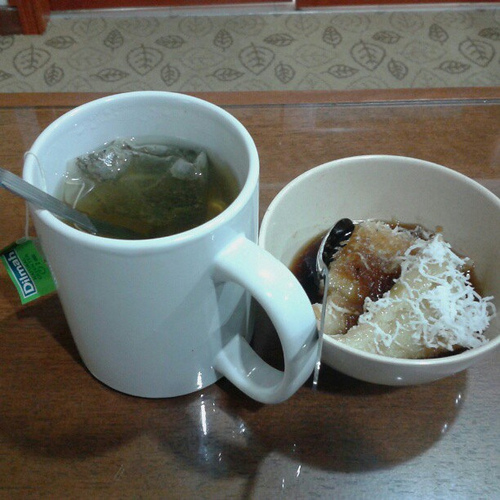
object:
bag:
[0, 240, 56, 306]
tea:
[83, 103, 227, 220]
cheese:
[411, 249, 486, 349]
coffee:
[295, 252, 326, 294]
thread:
[12, 152, 47, 242]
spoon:
[0, 167, 97, 232]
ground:
[269, 137, 317, 170]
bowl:
[258, 154, 500, 387]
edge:
[279, 455, 421, 475]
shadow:
[0, 383, 473, 481]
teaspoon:
[312, 217, 355, 385]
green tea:
[53, 137, 239, 241]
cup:
[22, 90, 319, 403]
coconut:
[330, 232, 496, 360]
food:
[311, 220, 497, 359]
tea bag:
[69, 137, 209, 232]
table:
[0, 91, 497, 500]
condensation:
[40, 101, 250, 178]